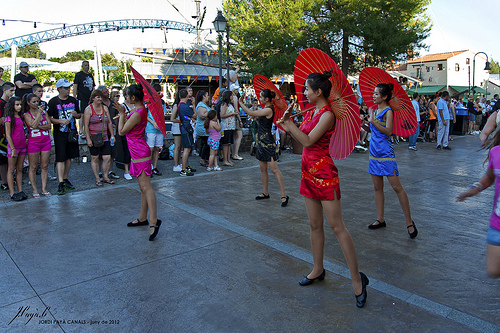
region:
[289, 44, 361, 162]
red umbrella being use in dance performance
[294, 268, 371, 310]
black shoes being worn by woman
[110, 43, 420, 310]
four women doing the same dance routine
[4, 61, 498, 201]
audience watching the dance performance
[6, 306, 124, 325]
text on lower left corner of image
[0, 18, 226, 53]
arch in the background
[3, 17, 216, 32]
hanging lights are off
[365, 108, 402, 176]
blue dress beign worn by woman dancer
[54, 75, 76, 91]
white cap beign worn by a man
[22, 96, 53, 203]
woman wearing a pink tank top and pink shorts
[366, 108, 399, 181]
a blue satin dress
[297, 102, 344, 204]
a red satin dress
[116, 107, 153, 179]
a pink satin dress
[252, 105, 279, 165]
a black satin dress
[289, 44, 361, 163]
the umbrellas are all red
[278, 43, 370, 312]
the young woman is wearing a red dress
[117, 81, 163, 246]
the young woman is wearing black shoes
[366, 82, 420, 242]
the young woman has dark hair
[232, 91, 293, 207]
the young woman is waving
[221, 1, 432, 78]
the tree is green and leafy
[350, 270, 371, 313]
black dancing show on left foot of woman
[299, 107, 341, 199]
red dancer outfit on woman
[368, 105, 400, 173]
blue dancer outfit on woman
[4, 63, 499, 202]
spectators watching the performance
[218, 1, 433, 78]
large green tree in background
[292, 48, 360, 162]
red umbrella is being used for performance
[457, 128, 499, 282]
woman is on her knees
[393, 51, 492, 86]
building in the background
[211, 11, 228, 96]
street light is turned off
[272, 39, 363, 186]
the woman is holding an umbrella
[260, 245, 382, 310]
the shoes are black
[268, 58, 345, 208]
woman wearing a red dress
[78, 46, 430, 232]
the women all have dresses on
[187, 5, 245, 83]
a green street light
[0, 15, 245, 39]
lights on a wire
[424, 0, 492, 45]
the sky is partly cloudy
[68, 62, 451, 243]
the woman are in motion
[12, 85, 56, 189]
the woman is wearing pink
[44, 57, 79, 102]
man wearing a baseball cap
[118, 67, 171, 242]
WOMAN IN A PINK DRESS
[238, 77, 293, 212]
WOMAN IN A BLACK DRESS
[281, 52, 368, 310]
WOMAN IN A RED DRESS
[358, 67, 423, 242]
WOMAN IN A BLUE DRESS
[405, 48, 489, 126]
BUILDING WITH GREEN AWNINGS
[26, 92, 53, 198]
WOMAN IN PINK SHORTS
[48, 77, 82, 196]
MAN WEARING BLACK SNEAKERS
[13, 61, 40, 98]
MAN CROSSING HIS ARMS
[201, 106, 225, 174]
GIRL IN PINK SHIRT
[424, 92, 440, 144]
PERSON IN ORANGE TOP